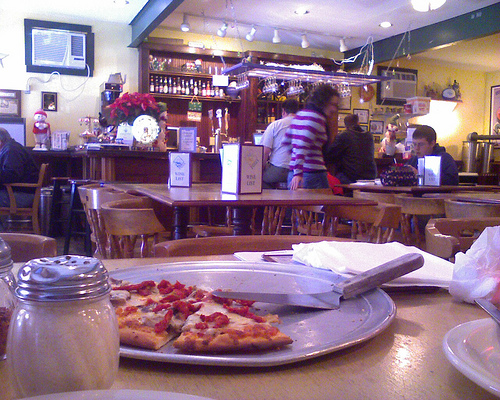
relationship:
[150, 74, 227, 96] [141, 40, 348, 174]
liquor in shelves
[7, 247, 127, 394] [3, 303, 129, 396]
container of parmesan cheese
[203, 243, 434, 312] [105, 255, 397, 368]
spatula to serve pizza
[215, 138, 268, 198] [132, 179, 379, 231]
menu on table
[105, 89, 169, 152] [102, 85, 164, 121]
flowers in a bouquet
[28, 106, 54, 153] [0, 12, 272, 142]
snowman in background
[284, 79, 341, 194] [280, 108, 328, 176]
woman with striped shirt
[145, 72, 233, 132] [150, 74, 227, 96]
shelf with bottles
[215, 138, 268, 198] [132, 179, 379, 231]
menu on empty table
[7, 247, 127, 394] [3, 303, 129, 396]
shaker has parmesan cheese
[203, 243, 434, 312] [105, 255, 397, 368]
spatula on pizza sheet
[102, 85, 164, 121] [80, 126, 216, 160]
poinsettias on bar counter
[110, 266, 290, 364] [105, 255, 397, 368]
pizza on baking tray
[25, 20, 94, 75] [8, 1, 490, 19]
air conditioning near ceiling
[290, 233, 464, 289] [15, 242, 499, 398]
napkins on table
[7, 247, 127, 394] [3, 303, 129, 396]
shaker has grated cheese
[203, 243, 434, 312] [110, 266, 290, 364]
spatula for pizza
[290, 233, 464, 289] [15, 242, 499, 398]
napkins on brown table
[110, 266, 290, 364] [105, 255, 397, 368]
pizza on a pizza pan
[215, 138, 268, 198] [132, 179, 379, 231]
menu standing on table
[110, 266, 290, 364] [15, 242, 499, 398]
pizza on brown table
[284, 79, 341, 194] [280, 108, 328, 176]
woman in striped shirt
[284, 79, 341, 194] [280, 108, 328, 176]
woman wears striped shirt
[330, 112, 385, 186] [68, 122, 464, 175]
man sitting at bar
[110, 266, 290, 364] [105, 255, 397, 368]
pizza on pizza tray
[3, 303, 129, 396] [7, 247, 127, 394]
parmesan cheese in glass shaker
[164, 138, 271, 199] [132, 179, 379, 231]
menus on wood table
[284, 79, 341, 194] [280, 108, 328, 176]
woman wearing long sleeve shirt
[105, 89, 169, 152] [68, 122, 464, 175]
flowers on top bar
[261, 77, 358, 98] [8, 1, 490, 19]
wine glasses hanging from ceiling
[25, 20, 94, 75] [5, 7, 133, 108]
air conditioning on wall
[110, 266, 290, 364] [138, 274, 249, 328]
pizza has red pepperonis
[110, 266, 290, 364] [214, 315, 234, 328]
pizza has red pepperoni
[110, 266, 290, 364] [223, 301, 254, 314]
pizza has red pepperoni